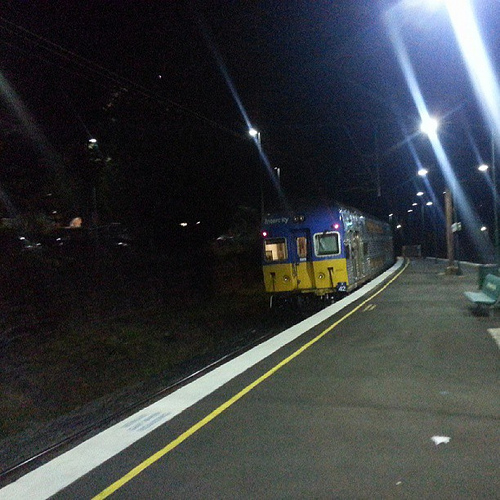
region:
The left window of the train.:
[267, 241, 286, 258]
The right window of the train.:
[310, 230, 340, 252]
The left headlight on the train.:
[277, 271, 295, 284]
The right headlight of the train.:
[314, 268, 331, 285]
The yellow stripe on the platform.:
[163, 214, 466, 499]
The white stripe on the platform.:
[120, 228, 418, 476]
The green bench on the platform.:
[464, 270, 499, 310]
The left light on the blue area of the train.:
[256, 227, 271, 237]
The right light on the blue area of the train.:
[326, 222, 343, 230]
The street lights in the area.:
[17, 32, 499, 249]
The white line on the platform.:
[15, 227, 417, 494]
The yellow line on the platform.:
[85, 243, 443, 480]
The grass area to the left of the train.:
[12, 245, 260, 395]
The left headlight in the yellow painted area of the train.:
[279, 272, 293, 285]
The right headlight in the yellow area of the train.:
[318, 267, 327, 284]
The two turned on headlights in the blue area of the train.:
[258, 219, 336, 234]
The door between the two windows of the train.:
[294, 228, 315, 285]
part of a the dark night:
[246, 67, 308, 170]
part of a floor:
[314, 394, 359, 443]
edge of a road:
[103, 390, 168, 445]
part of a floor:
[291, 397, 345, 469]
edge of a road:
[119, 390, 146, 410]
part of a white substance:
[421, 422, 444, 452]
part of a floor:
[333, 455, 368, 493]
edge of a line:
[140, 392, 202, 464]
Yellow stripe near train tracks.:
[290, 329, 331, 367]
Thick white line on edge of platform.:
[135, 389, 193, 446]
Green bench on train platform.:
[451, 275, 496, 334]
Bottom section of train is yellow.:
[251, 262, 343, 292]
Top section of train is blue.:
[257, 215, 339, 249]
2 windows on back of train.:
[258, 222, 373, 262]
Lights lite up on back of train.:
[256, 224, 354, 234]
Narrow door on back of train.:
[288, 222, 319, 322]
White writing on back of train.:
[258, 207, 313, 243]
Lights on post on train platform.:
[391, 150, 481, 205]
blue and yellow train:
[246, 181, 396, 301]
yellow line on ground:
[273, 343, 325, 383]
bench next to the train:
[458, 275, 496, 310]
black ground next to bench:
[368, 341, 423, 384]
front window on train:
[308, 223, 343, 264]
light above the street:
[380, 74, 450, 167]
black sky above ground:
[181, 40, 216, 62]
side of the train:
[356, 226, 388, 256]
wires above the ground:
[150, 96, 200, 139]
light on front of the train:
[306, 267, 333, 293]